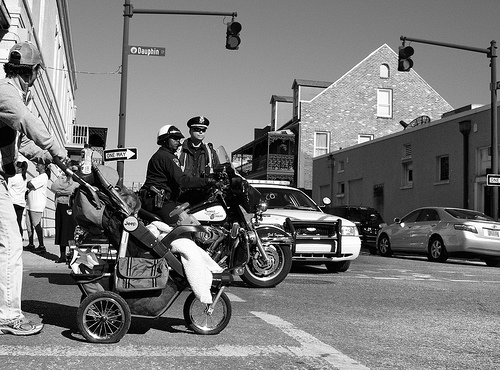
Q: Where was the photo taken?
A: It was taken at the street.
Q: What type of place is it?
A: It is a street.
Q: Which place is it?
A: It is a street.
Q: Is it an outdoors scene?
A: Yes, it is outdoors.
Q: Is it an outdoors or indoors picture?
A: It is outdoors.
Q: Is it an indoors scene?
A: No, it is outdoors.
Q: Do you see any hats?
A: Yes, there is a hat.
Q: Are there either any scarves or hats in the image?
A: Yes, there is a hat.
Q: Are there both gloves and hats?
A: No, there is a hat but no gloves.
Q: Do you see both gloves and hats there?
A: No, there is a hat but no gloves.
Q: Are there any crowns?
A: No, there are no crowns.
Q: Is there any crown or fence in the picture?
A: No, there are no crowns or fences.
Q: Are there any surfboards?
A: No, there are no surfboards.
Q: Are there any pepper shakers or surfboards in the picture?
A: No, there are no surfboards or pepper shakers.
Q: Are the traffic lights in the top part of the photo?
A: Yes, the traffic lights are in the top of the image.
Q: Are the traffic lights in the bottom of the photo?
A: No, the traffic lights are in the top of the image.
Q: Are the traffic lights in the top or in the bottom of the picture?
A: The traffic lights are in the top of the image.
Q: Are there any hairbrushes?
A: No, there are no hairbrushes.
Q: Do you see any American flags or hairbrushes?
A: No, there are no hairbrushes or American flags.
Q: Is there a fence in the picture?
A: No, there are no fences.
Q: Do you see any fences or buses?
A: No, there are no fences or buses.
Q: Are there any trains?
A: No, there are no trains.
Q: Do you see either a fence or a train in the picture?
A: No, there are no trains or fences.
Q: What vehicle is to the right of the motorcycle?
A: The vehicle is a car.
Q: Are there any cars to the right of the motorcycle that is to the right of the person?
A: Yes, there is a car to the right of the motorbike.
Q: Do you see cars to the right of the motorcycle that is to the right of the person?
A: Yes, there is a car to the right of the motorbike.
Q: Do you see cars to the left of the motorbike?
A: No, the car is to the right of the motorbike.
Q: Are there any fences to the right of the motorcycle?
A: No, there is a car to the right of the motorcycle.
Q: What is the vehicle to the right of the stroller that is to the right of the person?
A: The vehicle is a car.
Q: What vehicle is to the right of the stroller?
A: The vehicle is a car.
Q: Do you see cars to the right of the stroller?
A: Yes, there is a car to the right of the stroller.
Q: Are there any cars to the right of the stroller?
A: Yes, there is a car to the right of the stroller.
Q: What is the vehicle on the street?
A: The vehicle is a car.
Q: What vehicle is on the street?
A: The vehicle is a car.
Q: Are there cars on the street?
A: Yes, there is a car on the street.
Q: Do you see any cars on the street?
A: Yes, there is a car on the street.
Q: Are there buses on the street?
A: No, there is a car on the street.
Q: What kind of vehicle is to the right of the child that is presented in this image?
A: The vehicle is a car.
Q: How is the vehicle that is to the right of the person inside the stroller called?
A: The vehicle is a car.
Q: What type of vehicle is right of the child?
A: The vehicle is a car.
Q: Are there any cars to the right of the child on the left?
A: Yes, there is a car to the right of the child.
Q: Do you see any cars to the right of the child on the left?
A: Yes, there is a car to the right of the child.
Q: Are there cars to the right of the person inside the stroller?
A: Yes, there is a car to the right of the child.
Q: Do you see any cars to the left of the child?
A: No, the car is to the right of the child.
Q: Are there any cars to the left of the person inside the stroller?
A: No, the car is to the right of the child.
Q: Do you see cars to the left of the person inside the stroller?
A: No, the car is to the right of the child.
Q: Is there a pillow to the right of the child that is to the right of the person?
A: No, there is a car to the right of the child.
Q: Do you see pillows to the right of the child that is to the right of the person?
A: No, there is a car to the right of the child.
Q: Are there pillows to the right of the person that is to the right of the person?
A: No, there is a car to the right of the child.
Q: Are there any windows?
A: Yes, there is a window.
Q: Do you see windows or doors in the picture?
A: Yes, there is a window.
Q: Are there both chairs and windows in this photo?
A: No, there is a window but no chairs.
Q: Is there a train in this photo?
A: No, there are no trains.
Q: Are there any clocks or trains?
A: No, there are no trains or clocks.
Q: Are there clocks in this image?
A: No, there are no clocks.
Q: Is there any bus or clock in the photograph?
A: No, there are no clocks or buses.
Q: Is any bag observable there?
A: Yes, there is a bag.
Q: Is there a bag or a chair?
A: Yes, there is a bag.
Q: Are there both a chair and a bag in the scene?
A: No, there is a bag but no chairs.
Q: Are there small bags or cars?
A: Yes, there is a small bag.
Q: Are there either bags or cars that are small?
A: Yes, the bag is small.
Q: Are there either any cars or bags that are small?
A: Yes, the bag is small.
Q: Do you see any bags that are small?
A: Yes, there is a small bag.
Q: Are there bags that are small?
A: Yes, there is a bag that is small.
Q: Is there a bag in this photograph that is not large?
A: Yes, there is a small bag.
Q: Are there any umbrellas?
A: No, there are no umbrellas.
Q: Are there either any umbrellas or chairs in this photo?
A: No, there are no umbrellas or chairs.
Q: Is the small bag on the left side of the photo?
A: Yes, the bag is on the left of the image.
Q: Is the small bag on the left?
A: Yes, the bag is on the left of the image.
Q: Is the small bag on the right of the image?
A: No, the bag is on the left of the image.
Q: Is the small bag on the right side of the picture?
A: No, the bag is on the left of the image.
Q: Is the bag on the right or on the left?
A: The bag is on the left of the image.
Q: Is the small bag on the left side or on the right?
A: The bag is on the left of the image.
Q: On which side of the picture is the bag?
A: The bag is on the left of the image.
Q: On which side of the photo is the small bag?
A: The bag is on the left of the image.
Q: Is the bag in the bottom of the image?
A: Yes, the bag is in the bottom of the image.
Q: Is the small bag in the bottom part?
A: Yes, the bag is in the bottom of the image.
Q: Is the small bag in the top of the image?
A: No, the bag is in the bottom of the image.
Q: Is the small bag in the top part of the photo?
A: No, the bag is in the bottom of the image.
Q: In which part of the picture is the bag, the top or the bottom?
A: The bag is in the bottom of the image.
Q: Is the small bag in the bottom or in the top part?
A: The bag is in the bottom of the image.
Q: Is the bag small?
A: Yes, the bag is small.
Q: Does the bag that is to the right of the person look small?
A: Yes, the bag is small.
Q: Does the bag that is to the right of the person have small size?
A: Yes, the bag is small.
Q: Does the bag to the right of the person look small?
A: Yes, the bag is small.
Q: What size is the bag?
A: The bag is small.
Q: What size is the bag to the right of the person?
A: The bag is small.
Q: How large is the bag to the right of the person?
A: The bag is small.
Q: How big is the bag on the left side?
A: The bag is small.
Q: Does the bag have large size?
A: No, the bag is small.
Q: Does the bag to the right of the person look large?
A: No, the bag is small.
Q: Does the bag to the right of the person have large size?
A: No, the bag is small.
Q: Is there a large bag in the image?
A: No, there is a bag but it is small.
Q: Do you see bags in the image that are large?
A: No, there is a bag but it is small.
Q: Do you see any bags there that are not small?
A: No, there is a bag but it is small.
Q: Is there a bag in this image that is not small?
A: No, there is a bag but it is small.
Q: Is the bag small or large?
A: The bag is small.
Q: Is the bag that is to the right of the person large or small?
A: The bag is small.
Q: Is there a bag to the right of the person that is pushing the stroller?
A: Yes, there is a bag to the right of the person.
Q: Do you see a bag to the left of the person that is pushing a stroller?
A: No, the bag is to the right of the person.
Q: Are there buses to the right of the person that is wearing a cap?
A: No, there is a bag to the right of the person.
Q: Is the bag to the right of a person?
A: Yes, the bag is to the right of a person.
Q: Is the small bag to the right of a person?
A: Yes, the bag is to the right of a person.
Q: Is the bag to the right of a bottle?
A: No, the bag is to the right of a person.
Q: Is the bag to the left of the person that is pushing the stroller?
A: No, the bag is to the right of the person.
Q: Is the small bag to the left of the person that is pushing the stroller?
A: No, the bag is to the right of the person.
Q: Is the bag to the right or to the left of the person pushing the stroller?
A: The bag is to the right of the person.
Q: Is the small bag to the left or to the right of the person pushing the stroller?
A: The bag is to the right of the person.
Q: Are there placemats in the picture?
A: No, there are no placemats.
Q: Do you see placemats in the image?
A: No, there are no placemats.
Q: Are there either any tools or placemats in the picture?
A: No, there are no placemats or tools.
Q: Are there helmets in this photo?
A: Yes, there is a helmet.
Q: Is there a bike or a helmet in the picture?
A: Yes, there is a helmet.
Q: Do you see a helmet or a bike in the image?
A: Yes, there is a helmet.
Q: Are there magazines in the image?
A: No, there are no magazines.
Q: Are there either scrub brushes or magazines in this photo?
A: No, there are no magazines or scrub brushes.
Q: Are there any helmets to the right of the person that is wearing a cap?
A: Yes, there is a helmet to the right of the person.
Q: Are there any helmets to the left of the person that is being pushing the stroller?
A: No, the helmet is to the right of the person.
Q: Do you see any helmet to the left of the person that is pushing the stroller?
A: No, the helmet is to the right of the person.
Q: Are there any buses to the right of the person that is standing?
A: No, there is a helmet to the right of the person.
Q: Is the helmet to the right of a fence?
A: No, the helmet is to the right of a person.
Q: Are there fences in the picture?
A: No, there are no fences.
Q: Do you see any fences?
A: No, there are no fences.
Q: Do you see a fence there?
A: No, there are no fences.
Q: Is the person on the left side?
A: Yes, the person is on the left of the image.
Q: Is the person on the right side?
A: No, the person is on the left of the image.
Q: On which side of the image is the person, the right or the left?
A: The person is on the left of the image.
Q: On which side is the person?
A: The person is on the left of the image.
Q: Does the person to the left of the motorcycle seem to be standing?
A: Yes, the person is standing.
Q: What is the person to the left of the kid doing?
A: The person is standing.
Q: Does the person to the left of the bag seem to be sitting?
A: No, the person is standing.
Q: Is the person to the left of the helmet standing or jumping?
A: The person is standing.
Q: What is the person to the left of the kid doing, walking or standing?
A: The person is standing.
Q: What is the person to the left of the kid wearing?
A: The person is wearing a cap.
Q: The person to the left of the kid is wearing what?
A: The person is wearing a cap.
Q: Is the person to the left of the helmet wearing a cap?
A: Yes, the person is wearing a cap.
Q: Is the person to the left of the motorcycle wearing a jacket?
A: No, the person is wearing a cap.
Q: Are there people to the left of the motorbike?
A: Yes, there is a person to the left of the motorbike.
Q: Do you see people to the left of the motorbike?
A: Yes, there is a person to the left of the motorbike.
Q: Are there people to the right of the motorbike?
A: No, the person is to the left of the motorbike.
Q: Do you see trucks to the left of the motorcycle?
A: No, there is a person to the left of the motorcycle.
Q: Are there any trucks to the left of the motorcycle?
A: No, there is a person to the left of the motorcycle.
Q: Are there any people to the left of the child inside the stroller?
A: Yes, there is a person to the left of the child.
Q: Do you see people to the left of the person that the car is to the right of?
A: Yes, there is a person to the left of the child.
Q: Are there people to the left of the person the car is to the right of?
A: Yes, there is a person to the left of the child.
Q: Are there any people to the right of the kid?
A: No, the person is to the left of the kid.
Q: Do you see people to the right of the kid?
A: No, the person is to the left of the kid.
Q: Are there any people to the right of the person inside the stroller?
A: No, the person is to the left of the kid.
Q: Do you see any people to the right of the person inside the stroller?
A: No, the person is to the left of the kid.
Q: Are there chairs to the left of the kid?
A: No, there is a person to the left of the kid.